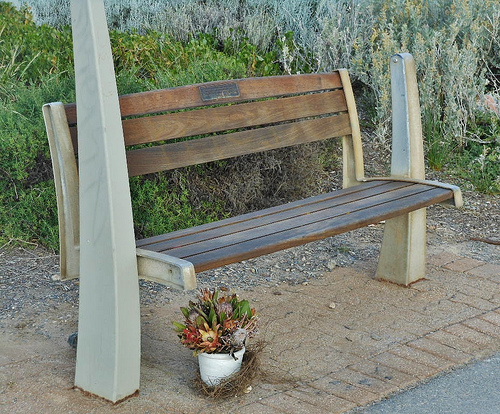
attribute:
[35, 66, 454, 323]
bench — wooden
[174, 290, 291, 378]
leaves — green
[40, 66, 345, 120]
planks — wooden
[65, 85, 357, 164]
planks — wooden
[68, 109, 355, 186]
planks — wooden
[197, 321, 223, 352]
flower — red, yellow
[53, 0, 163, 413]
pole — green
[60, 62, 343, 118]
board — wooden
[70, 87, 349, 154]
board — wooden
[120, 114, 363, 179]
board — wooden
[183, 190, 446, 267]
board — wooden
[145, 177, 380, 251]
board — wooden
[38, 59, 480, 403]
bench — wooden, brown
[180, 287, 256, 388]
plant — potted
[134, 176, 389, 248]
board — brown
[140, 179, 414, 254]
board — brown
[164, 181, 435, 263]
board — brown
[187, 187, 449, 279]
board — brown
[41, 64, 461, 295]
bench — wooden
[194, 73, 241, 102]
plaque — black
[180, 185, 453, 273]
plank — wooden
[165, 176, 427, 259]
plank — wooden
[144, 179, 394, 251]
plank — wooden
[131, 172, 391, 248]
plank — wooden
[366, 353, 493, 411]
ground — cement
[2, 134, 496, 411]
sidewalk — bricked